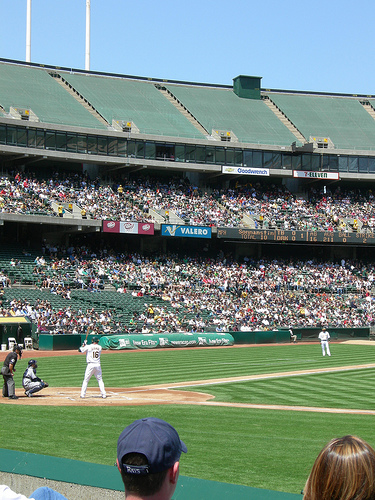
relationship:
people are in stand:
[13, 175, 353, 223] [8, 209, 370, 250]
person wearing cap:
[102, 406, 187, 496] [104, 413, 193, 473]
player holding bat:
[67, 320, 113, 401] [78, 323, 95, 348]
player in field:
[67, 320, 113, 401] [5, 331, 374, 477]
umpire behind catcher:
[0, 335, 27, 403] [16, 356, 56, 404]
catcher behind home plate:
[16, 356, 56, 404] [65, 392, 125, 403]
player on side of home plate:
[67, 320, 113, 401] [65, 392, 125, 403]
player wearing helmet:
[16, 356, 56, 404] [23, 359, 44, 371]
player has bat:
[67, 320, 113, 401] [78, 323, 95, 348]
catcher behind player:
[16, 356, 56, 404] [67, 320, 113, 401]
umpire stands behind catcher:
[0, 335, 27, 403] [16, 356, 56, 404]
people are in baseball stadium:
[13, 175, 353, 223] [4, 57, 364, 356]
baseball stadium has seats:
[4, 57, 364, 356] [4, 248, 188, 338]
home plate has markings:
[65, 392, 125, 403] [108, 392, 138, 403]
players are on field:
[4, 338, 126, 402] [5, 331, 374, 477]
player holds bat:
[67, 320, 113, 401] [78, 323, 95, 348]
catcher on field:
[16, 356, 56, 404] [5, 331, 374, 477]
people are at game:
[13, 175, 353, 223] [2, 330, 346, 468]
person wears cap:
[102, 406, 187, 496] [104, 413, 193, 473]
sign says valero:
[157, 221, 216, 244] [175, 227, 209, 235]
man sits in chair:
[289, 327, 301, 343] [285, 333, 290, 341]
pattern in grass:
[239, 380, 352, 404] [132, 358, 344, 446]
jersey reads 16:
[82, 342, 103, 363] [92, 349, 99, 359]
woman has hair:
[295, 431, 374, 497] [328, 451, 357, 485]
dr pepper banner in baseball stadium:
[95, 217, 158, 238] [4, 57, 364, 356]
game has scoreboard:
[2, 330, 346, 468] [216, 220, 374, 247]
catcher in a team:
[16, 356, 56, 404] [302, 327, 373, 404]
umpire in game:
[0, 335, 27, 403] [2, 330, 346, 468]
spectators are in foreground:
[13, 430, 373, 497] [8, 412, 374, 494]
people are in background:
[13, 175, 353, 223] [10, 93, 355, 329]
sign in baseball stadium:
[157, 221, 216, 244] [4, 57, 364, 356]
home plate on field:
[65, 392, 125, 403] [5, 331, 374, 477]